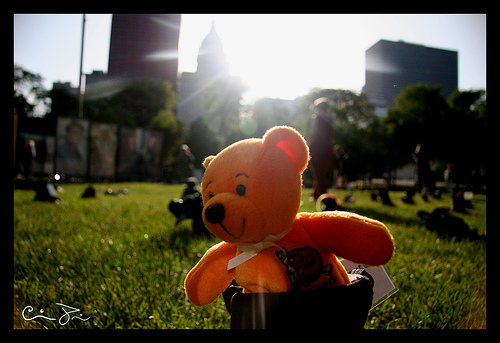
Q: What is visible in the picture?
A: A toy bear is visible in the picture.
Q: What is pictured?
A: Toy.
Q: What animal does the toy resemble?
A: Bear.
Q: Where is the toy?
A: Park.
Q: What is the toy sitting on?
A: Grass.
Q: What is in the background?
A: Buildings.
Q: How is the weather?
A: Clear.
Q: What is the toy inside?
A: Bucket.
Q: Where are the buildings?
A: Behind the toy.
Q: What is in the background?
A: The sun.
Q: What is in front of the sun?
A: Buildings.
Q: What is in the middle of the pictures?
A: A teddy bear.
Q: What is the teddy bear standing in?
A: A pot.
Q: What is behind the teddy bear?
A: Other people.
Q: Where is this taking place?
A: A grassy field.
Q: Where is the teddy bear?
A: In a bucket.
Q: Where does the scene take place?
A: At a park.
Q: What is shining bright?
A: Sun.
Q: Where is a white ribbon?
A: Around bear's neck.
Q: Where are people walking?
A: On the grass.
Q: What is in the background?
A: Buildings.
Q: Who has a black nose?
A: Teddy bear.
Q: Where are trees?
A: In the distance.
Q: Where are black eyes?
A: On teddy's face.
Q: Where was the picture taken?
A: The park.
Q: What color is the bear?
A: Orange.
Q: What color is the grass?
A: Green.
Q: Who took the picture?
A: A friend.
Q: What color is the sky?
A: Clear.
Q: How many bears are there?
A: One.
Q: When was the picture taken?
A: Midday.